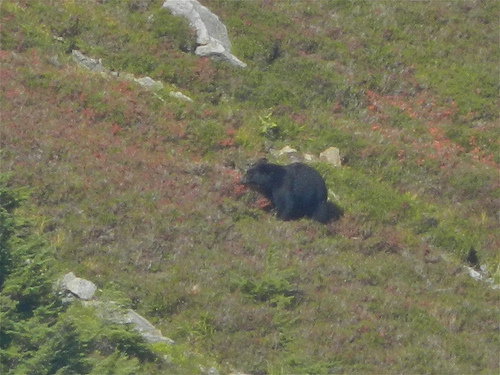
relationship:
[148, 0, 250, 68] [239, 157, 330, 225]
rock beside bear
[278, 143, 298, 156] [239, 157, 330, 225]
rock beside bear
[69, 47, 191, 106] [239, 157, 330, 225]
rock beside bear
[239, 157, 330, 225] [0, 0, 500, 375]
bear in hill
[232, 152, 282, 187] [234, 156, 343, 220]
head on animal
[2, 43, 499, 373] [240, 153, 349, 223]
grass in front of animal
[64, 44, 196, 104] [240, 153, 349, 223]
rocks above animal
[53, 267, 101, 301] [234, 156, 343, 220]
rock above animal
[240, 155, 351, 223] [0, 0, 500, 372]
bear on hill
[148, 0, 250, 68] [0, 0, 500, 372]
rock on hill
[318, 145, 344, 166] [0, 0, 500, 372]
rock on hill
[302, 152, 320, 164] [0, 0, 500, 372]
rock on hill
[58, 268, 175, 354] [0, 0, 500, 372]
rock on hill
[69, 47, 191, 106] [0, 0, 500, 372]
rock on hill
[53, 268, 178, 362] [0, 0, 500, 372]
rock on hill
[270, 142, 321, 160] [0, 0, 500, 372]
rock on hill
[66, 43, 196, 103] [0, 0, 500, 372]
rock on hill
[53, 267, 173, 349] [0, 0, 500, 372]
rock on hill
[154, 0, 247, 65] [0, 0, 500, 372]
rock on hill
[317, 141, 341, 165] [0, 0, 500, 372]
rock on hill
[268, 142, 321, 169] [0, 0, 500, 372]
rock on hill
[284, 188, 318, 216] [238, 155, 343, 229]
stomach on bear